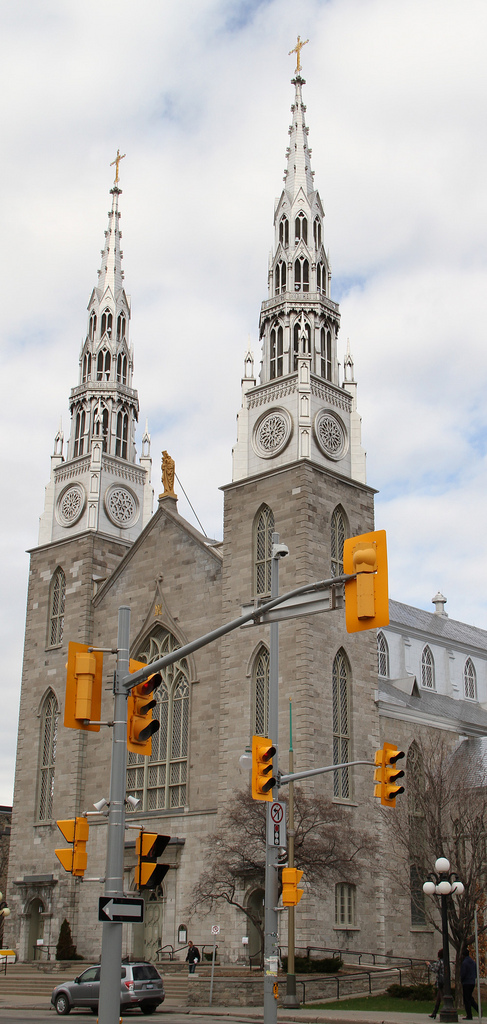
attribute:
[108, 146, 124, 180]
cross — gold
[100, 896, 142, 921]
arrow — white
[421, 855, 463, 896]
lamps — white